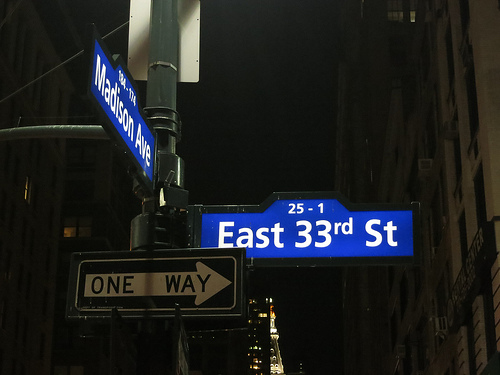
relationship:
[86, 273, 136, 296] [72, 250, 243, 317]
one way sign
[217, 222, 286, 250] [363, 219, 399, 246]
east rd st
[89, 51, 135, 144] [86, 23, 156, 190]
madison ave sign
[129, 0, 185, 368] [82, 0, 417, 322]
pole holding signs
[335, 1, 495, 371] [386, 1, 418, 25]
building with lights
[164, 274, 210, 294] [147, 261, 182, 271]
way written black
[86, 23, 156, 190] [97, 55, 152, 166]
blue and white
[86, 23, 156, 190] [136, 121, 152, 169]
sign madison ave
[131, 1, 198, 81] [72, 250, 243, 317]
back of sign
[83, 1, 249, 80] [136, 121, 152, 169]
above madison ave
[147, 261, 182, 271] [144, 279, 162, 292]
black and white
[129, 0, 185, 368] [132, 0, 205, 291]
silver street marker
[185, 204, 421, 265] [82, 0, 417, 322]
lit street signs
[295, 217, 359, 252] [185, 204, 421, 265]
33rd street sign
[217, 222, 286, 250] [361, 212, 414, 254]
east rd street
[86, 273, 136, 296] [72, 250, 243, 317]
one way street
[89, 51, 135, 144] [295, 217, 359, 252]
madison and 33rd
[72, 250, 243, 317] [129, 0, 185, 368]
sign on pole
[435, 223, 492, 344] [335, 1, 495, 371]
sign on building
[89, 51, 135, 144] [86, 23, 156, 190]
madison avenue sign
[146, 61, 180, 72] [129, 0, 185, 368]
strap on pole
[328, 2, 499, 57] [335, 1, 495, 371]
top of building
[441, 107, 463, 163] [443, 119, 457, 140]
window air conditioner